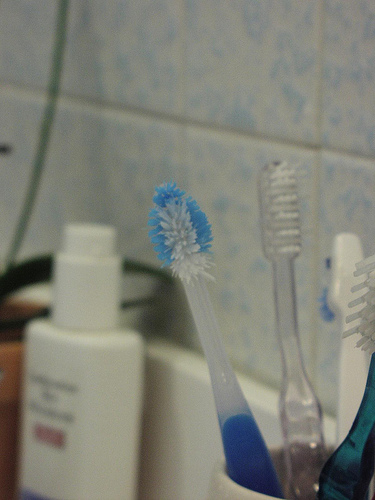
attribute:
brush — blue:
[185, 414, 302, 496]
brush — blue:
[180, 362, 330, 466]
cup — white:
[176, 446, 239, 493]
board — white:
[122, 397, 244, 451]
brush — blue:
[206, 400, 304, 497]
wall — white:
[160, 387, 244, 487]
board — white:
[79, 383, 233, 463]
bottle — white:
[27, 187, 162, 497]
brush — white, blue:
[136, 214, 304, 497]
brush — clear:
[253, 233, 355, 498]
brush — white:
[315, 236, 373, 394]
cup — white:
[193, 420, 373, 498]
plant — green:
[24, 61, 95, 176]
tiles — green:
[116, 45, 281, 145]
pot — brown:
[6, 294, 40, 424]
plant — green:
[18, 59, 86, 258]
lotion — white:
[28, 215, 139, 496]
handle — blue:
[208, 413, 287, 493]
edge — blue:
[214, 419, 233, 478]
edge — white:
[129, 385, 142, 492]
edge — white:
[216, 467, 235, 494]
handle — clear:
[284, 394, 324, 467]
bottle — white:
[117, 404, 138, 483]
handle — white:
[201, 338, 241, 397]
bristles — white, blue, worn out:
[152, 192, 215, 282]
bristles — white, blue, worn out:
[144, 194, 217, 282]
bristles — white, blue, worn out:
[143, 187, 218, 281]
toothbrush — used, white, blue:
[134, 176, 282, 493]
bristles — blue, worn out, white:
[147, 174, 215, 281]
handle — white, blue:
[178, 282, 282, 483]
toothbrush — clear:
[253, 159, 328, 495]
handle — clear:
[261, 262, 323, 483]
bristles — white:
[255, 156, 304, 263]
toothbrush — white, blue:
[319, 223, 368, 423]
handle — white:
[335, 326, 369, 455]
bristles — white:
[321, 251, 333, 323]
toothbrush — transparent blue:
[317, 356, 372, 490]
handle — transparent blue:
[321, 479, 372, 491]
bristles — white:
[345, 267, 368, 355]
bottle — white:
[57, 231, 131, 487]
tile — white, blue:
[186, 137, 256, 193]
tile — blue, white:
[86, 147, 128, 213]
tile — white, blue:
[200, 72, 272, 119]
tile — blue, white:
[118, 69, 187, 104]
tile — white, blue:
[327, 165, 374, 225]